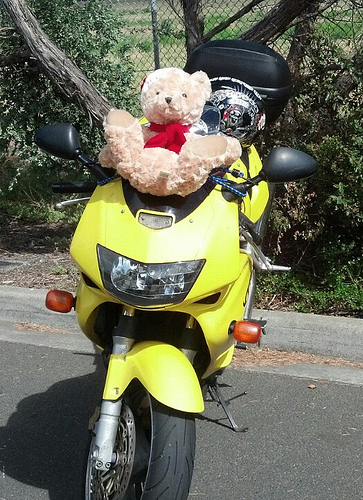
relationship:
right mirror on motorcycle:
[259, 145, 321, 183] [40, 50, 318, 498]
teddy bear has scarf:
[88, 65, 244, 195] [142, 120, 187, 152]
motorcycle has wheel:
[40, 50, 318, 498] [76, 383, 195, 498]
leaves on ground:
[270, 336, 325, 368] [0, 343, 350, 494]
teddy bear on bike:
[97, 65, 244, 195] [12, 33, 342, 496]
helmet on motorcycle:
[201, 66, 261, 143] [33, 41, 318, 499]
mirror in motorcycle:
[19, 92, 83, 180] [26, 73, 349, 488]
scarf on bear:
[142, 117, 188, 153] [99, 66, 241, 199]